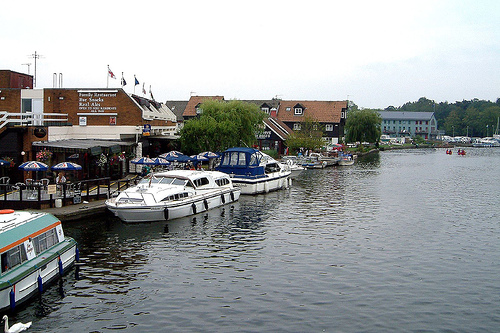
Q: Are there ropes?
A: No, there are no ropes.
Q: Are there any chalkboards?
A: No, there are no chalkboards.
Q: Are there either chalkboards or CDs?
A: No, there are no chalkboards or cds.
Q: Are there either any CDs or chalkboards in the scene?
A: No, there are no chalkboards or cds.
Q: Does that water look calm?
A: Yes, the water is calm.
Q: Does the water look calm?
A: Yes, the water is calm.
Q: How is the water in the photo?
A: The water is calm.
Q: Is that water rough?
A: No, the water is calm.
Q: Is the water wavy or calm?
A: The water is calm.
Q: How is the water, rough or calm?
A: The water is calm.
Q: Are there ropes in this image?
A: No, there are no ropes.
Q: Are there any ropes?
A: No, there are no ropes.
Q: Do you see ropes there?
A: No, there are no ropes.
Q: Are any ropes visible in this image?
A: No, there are no ropes.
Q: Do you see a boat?
A: Yes, there is a boat.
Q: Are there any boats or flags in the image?
A: Yes, there is a boat.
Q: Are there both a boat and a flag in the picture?
A: Yes, there are both a boat and a flag.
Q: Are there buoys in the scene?
A: No, there are no buoys.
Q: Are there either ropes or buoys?
A: No, there are no buoys or ropes.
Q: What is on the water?
A: The boat is on the water.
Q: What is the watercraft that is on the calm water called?
A: The watercraft is a boat.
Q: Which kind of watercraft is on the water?
A: The watercraft is a boat.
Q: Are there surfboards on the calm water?
A: No, there is a boat on the water.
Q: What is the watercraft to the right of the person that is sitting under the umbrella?
A: The watercraft is a boat.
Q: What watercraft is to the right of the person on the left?
A: The watercraft is a boat.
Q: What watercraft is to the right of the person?
A: The watercraft is a boat.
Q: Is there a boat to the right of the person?
A: Yes, there is a boat to the right of the person.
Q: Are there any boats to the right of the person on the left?
A: Yes, there is a boat to the right of the person.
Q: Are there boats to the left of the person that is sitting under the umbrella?
A: No, the boat is to the right of the person.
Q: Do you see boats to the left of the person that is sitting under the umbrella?
A: No, the boat is to the right of the person.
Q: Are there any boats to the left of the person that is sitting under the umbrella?
A: No, the boat is to the right of the person.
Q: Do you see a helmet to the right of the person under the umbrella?
A: No, there is a boat to the right of the person.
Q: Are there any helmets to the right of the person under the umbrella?
A: No, there is a boat to the right of the person.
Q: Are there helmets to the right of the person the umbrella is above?
A: No, there is a boat to the right of the person.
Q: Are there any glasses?
A: No, there are no glasses.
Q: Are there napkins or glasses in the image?
A: No, there are no glasses or napkins.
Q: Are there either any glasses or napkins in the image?
A: No, there are no glasses or napkins.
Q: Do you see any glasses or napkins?
A: No, there are no glasses or napkins.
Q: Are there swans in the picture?
A: Yes, there is a swan.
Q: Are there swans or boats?
A: Yes, there is a swan.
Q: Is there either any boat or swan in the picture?
A: Yes, there is a swan.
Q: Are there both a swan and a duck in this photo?
A: No, there is a swan but no ducks.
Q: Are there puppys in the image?
A: No, there are no puppys.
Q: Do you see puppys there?
A: No, there are no puppys.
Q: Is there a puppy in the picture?
A: No, there are no puppys.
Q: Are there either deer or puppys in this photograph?
A: No, there are no puppys or deer.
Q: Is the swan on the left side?
A: Yes, the swan is on the left of the image.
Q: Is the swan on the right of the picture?
A: No, the swan is on the left of the image.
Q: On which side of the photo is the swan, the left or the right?
A: The swan is on the left of the image.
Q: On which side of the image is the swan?
A: The swan is on the left of the image.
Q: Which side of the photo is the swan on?
A: The swan is on the left of the image.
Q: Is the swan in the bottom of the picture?
A: Yes, the swan is in the bottom of the image.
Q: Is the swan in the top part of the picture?
A: No, the swan is in the bottom of the image.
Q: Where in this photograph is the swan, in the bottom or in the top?
A: The swan is in the bottom of the image.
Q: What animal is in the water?
A: The swan is in the water.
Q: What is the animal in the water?
A: The animal is a swan.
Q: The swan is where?
A: The swan is in the water.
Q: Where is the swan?
A: The swan is in the water.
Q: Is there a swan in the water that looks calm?
A: Yes, there is a swan in the water.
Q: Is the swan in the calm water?
A: Yes, the swan is in the water.